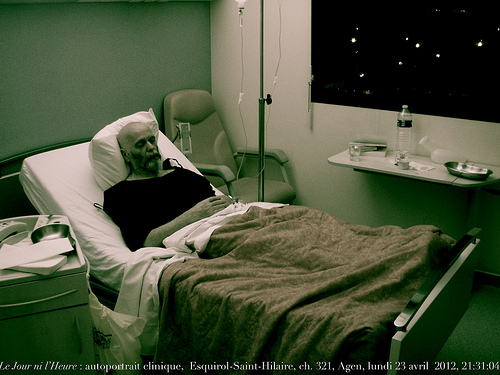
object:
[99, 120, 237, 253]
man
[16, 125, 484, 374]
bed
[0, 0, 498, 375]
hospital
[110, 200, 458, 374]
blanket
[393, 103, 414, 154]
bottle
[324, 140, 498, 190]
shelf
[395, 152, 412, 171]
water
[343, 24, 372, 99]
lights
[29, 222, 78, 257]
bed pan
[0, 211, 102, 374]
table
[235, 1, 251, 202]
tubing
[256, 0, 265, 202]
post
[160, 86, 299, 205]
chair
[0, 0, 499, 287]
walls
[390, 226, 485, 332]
rail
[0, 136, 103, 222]
headboard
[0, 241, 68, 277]
book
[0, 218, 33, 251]
phone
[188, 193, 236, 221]
hands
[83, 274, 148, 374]
plastic bag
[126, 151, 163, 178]
facial hair